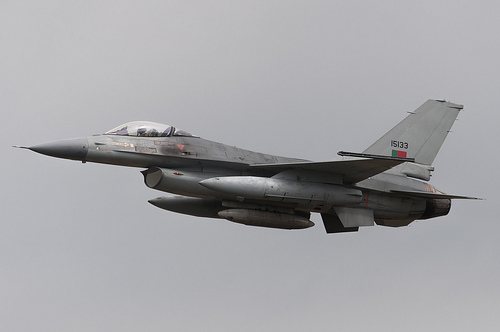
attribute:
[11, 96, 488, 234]
fighter jet — grey, gray, large, flying, silver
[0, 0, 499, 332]
sky — overcast, gray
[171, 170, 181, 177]
light — red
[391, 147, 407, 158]
rectangle — red, green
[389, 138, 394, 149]
number — black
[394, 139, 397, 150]
number — black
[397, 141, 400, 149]
number — black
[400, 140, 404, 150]
number — black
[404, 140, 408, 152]
number — black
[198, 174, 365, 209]
missile — large